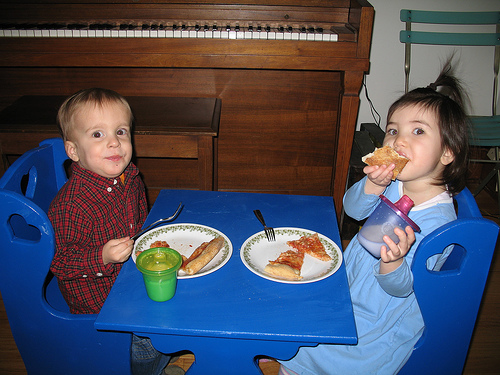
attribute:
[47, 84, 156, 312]
boy — small, checked, toddler, little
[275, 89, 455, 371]
girl — little, toddler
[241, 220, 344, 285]
lunch — white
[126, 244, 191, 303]
spillproofcup — green, blue, plastic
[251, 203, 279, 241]
fork — metal, silver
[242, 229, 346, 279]
plate — white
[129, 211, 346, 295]
plates — white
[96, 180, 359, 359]
table — blue, cloloredblue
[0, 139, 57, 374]
chair — childchair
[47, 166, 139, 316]
shirtflannel — red, checked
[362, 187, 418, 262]
sipycup — halffull, plastic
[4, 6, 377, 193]
piano — wooden, brown, large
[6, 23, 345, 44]
pianokeys — white, black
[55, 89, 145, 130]
hair — brown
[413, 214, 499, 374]
childrenchair — blue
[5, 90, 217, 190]
bench — wooden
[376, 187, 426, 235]
lid — red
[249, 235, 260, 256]
decoration — green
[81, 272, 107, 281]
buttons — white